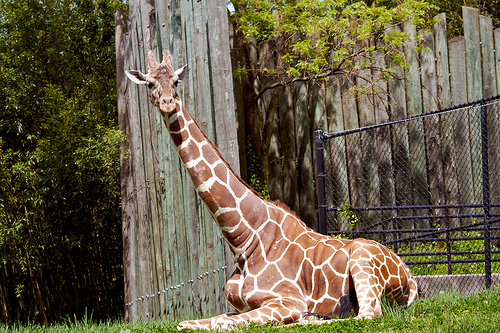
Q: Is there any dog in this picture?
A: No, there are no dogs.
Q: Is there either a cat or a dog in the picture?
A: No, there are no dogs or cats.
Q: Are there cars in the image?
A: No, there are no cars.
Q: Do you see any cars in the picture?
A: No, there are no cars.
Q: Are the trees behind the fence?
A: Yes, the trees are behind the fence.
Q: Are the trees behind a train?
A: No, the trees are behind the fence.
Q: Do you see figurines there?
A: No, there are no figurines.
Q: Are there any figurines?
A: No, there are no figurines.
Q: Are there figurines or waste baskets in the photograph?
A: No, there are no figurines or waste baskets.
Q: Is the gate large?
A: Yes, the gate is large.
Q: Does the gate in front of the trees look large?
A: Yes, the gate is large.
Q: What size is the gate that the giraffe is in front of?
A: The gate is large.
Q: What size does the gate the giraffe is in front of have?
A: The gate has large size.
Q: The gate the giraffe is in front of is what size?
A: The gate is large.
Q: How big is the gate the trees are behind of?
A: The gate is large.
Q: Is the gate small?
A: No, the gate is large.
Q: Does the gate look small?
A: No, the gate is large.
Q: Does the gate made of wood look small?
A: No, the gate is large.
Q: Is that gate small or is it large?
A: The gate is large.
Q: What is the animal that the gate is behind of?
A: The animal is a giraffe.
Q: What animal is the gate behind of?
A: The gate is behind the giraffe.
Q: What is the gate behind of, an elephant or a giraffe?
A: The gate is behind a giraffe.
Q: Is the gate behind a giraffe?
A: Yes, the gate is behind a giraffe.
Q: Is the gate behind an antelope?
A: No, the gate is behind a giraffe.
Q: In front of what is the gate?
A: The gate is in front of the trees.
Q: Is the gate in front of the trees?
A: Yes, the gate is in front of the trees.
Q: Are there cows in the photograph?
A: No, there are no cows.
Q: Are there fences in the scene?
A: Yes, there is a fence.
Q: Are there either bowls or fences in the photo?
A: Yes, there is a fence.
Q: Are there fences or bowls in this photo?
A: Yes, there is a fence.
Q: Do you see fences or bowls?
A: Yes, there is a fence.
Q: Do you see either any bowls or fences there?
A: Yes, there is a fence.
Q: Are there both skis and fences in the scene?
A: No, there is a fence but no skis.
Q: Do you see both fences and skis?
A: No, there is a fence but no skis.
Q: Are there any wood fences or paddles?
A: Yes, there is a wood fence.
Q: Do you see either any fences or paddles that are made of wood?
A: Yes, the fence is made of wood.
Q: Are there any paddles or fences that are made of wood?
A: Yes, the fence is made of wood.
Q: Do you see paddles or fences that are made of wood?
A: Yes, the fence is made of wood.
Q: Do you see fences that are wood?
A: Yes, there is a wood fence.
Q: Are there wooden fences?
A: Yes, there is a wood fence.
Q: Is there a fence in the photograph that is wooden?
A: Yes, there is a fence that is wooden.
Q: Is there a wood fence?
A: Yes, there is a fence that is made of wood.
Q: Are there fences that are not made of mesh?
A: Yes, there is a fence that is made of wood.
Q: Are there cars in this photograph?
A: No, there are no cars.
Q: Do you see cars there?
A: No, there are no cars.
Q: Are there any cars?
A: No, there are no cars.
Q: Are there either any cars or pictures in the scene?
A: No, there are no cars or pictures.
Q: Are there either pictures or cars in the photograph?
A: No, there are no cars or pictures.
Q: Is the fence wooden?
A: Yes, the fence is wooden.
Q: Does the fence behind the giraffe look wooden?
A: Yes, the fence is wooden.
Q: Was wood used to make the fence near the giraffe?
A: Yes, the fence is made of wood.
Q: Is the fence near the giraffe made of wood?
A: Yes, the fence is made of wood.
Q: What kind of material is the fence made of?
A: The fence is made of wood.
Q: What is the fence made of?
A: The fence is made of wood.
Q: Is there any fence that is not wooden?
A: No, there is a fence but it is wooden.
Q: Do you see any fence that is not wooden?
A: No, there is a fence but it is wooden.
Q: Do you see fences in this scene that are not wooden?
A: No, there is a fence but it is wooden.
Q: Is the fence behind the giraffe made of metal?
A: No, the fence is made of wood.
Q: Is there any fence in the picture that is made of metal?
A: No, there is a fence but it is made of wood.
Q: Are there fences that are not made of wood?
A: No, there is a fence but it is made of wood.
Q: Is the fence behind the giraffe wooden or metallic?
A: The fence is wooden.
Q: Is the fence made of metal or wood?
A: The fence is made of wood.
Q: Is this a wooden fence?
A: Yes, this is a wooden fence.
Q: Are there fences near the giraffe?
A: Yes, there is a fence near the giraffe.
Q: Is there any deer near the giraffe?
A: No, there is a fence near the giraffe.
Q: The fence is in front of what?
A: The fence is in front of the trees.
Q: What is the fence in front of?
A: The fence is in front of the trees.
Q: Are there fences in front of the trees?
A: Yes, there is a fence in front of the trees.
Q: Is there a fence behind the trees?
A: No, the fence is in front of the trees.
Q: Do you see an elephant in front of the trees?
A: No, there is a fence in front of the trees.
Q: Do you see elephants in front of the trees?
A: No, there is a fence in front of the trees.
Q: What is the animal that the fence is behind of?
A: The animal is a giraffe.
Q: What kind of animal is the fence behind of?
A: The fence is behind the giraffe.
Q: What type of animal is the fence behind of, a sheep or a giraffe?
A: The fence is behind a giraffe.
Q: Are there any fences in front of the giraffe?
A: No, the fence is behind the giraffe.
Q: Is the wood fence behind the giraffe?
A: Yes, the fence is behind the giraffe.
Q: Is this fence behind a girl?
A: No, the fence is behind the giraffe.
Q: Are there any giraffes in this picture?
A: Yes, there is a giraffe.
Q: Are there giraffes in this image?
A: Yes, there is a giraffe.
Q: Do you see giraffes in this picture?
A: Yes, there is a giraffe.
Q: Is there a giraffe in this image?
A: Yes, there is a giraffe.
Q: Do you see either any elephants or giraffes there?
A: Yes, there is a giraffe.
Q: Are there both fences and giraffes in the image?
A: Yes, there are both a giraffe and a fence.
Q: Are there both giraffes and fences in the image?
A: Yes, there are both a giraffe and a fence.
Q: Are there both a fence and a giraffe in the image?
A: Yes, there are both a giraffe and a fence.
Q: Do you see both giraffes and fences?
A: Yes, there are both a giraffe and a fence.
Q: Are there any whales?
A: No, there are no whales.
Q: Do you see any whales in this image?
A: No, there are no whales.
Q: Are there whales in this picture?
A: No, there are no whales.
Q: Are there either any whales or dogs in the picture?
A: No, there are no whales or dogs.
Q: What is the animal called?
A: The animal is a giraffe.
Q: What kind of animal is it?
A: The animal is a giraffe.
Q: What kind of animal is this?
A: This is a giraffe.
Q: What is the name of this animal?
A: This is a giraffe.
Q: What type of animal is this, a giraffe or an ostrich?
A: This is a giraffe.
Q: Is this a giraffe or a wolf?
A: This is a giraffe.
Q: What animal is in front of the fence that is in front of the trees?
A: The giraffe is in front of the fence.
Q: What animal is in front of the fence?
A: The giraffe is in front of the fence.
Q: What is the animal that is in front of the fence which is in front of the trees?
A: The animal is a giraffe.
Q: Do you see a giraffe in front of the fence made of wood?
A: Yes, there is a giraffe in front of the fence.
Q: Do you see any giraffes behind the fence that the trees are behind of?
A: No, the giraffe is in front of the fence.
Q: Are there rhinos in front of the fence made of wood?
A: No, there is a giraffe in front of the fence.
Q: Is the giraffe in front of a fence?
A: Yes, the giraffe is in front of a fence.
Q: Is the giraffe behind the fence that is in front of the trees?
A: No, the giraffe is in front of the fence.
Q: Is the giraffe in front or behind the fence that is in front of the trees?
A: The giraffe is in front of the fence.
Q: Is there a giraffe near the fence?
A: Yes, there is a giraffe near the fence.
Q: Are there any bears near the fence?
A: No, there is a giraffe near the fence.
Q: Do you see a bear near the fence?
A: No, there is a giraffe near the fence.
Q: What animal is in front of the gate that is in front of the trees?
A: The giraffe is in front of the gate.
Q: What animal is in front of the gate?
A: The giraffe is in front of the gate.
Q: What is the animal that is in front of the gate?
A: The animal is a giraffe.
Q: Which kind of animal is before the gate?
A: The animal is a giraffe.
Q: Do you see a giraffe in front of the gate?
A: Yes, there is a giraffe in front of the gate.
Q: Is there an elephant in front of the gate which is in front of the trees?
A: No, there is a giraffe in front of the gate.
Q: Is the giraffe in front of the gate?
A: Yes, the giraffe is in front of the gate.